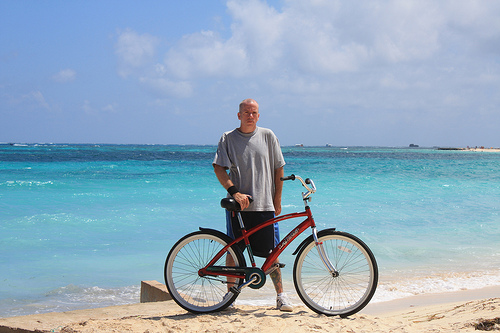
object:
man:
[210, 96, 293, 311]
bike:
[164, 174, 379, 318]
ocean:
[1, 142, 497, 314]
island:
[436, 144, 499, 154]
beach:
[0, 280, 500, 333]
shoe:
[276, 296, 295, 312]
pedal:
[228, 286, 241, 296]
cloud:
[114, 25, 163, 79]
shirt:
[212, 125, 286, 212]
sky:
[1, 1, 498, 149]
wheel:
[292, 231, 379, 319]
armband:
[227, 186, 241, 198]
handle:
[279, 173, 295, 181]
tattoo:
[269, 268, 283, 292]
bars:
[305, 178, 312, 184]